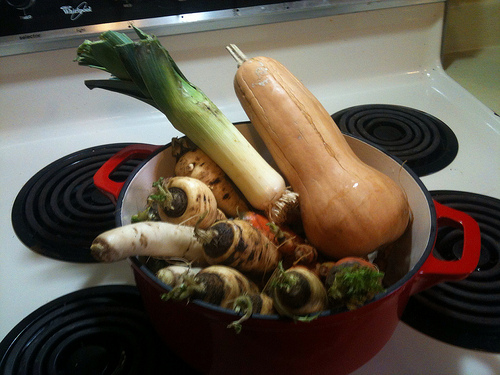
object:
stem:
[69, 23, 189, 111]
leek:
[72, 20, 299, 229]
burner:
[398, 188, 499, 354]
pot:
[90, 120, 480, 374]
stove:
[0, 0, 500, 375]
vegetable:
[70, 21, 416, 337]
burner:
[11, 142, 156, 265]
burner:
[0, 284, 178, 375]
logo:
[59, 1, 95, 22]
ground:
[295, 118, 349, 164]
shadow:
[376, 217, 412, 287]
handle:
[418, 197, 482, 283]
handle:
[93, 144, 157, 201]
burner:
[329, 102, 458, 178]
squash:
[223, 40, 410, 261]